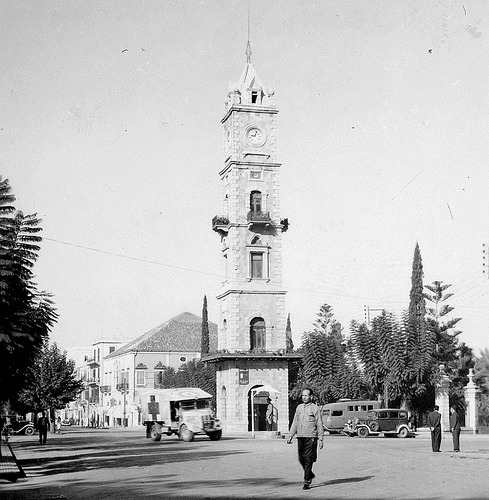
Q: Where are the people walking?
A: The road.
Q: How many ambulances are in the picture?
A: One.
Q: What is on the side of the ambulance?
A: A cross.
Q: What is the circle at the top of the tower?
A: A clock.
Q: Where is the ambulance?
A: The road.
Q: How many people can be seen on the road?
A: 4.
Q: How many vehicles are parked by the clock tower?
A: Two.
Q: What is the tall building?
A: Tower.